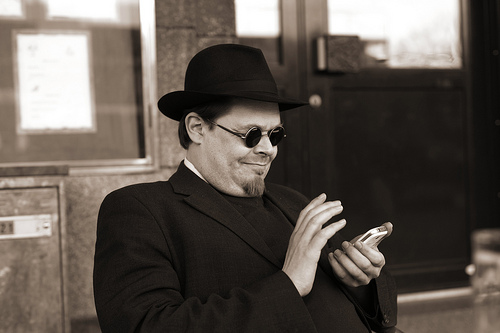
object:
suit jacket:
[88, 172, 401, 331]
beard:
[242, 175, 272, 200]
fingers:
[294, 191, 346, 250]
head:
[174, 99, 288, 200]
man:
[89, 42, 398, 332]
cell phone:
[352, 221, 387, 258]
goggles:
[207, 118, 285, 151]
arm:
[90, 184, 350, 331]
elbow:
[92, 297, 191, 329]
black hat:
[155, 40, 310, 120]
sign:
[17, 35, 92, 130]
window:
[0, 0, 158, 178]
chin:
[229, 172, 269, 202]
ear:
[181, 110, 205, 145]